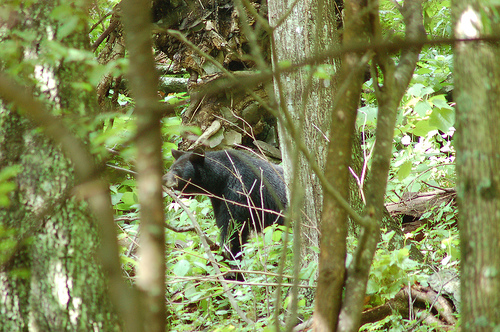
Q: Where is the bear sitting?
A: The woods.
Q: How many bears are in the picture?
A: One.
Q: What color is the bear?
A: Black.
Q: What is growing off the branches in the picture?
A: Leaves.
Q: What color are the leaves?
A: Green.